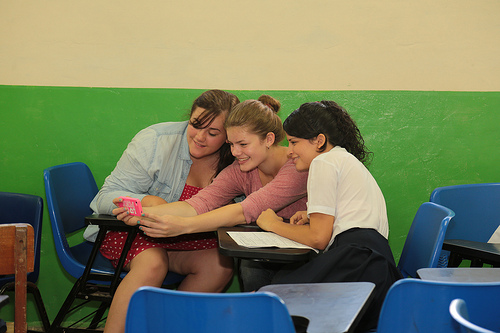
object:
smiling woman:
[255, 97, 402, 332]